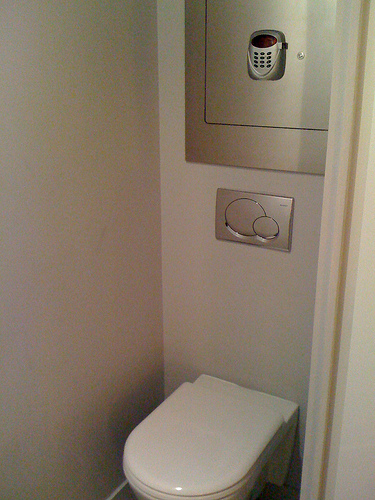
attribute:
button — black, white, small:
[252, 53, 258, 59]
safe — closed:
[203, 0, 337, 130]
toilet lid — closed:
[119, 370, 287, 498]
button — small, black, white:
[265, 50, 271, 55]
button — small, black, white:
[264, 56, 273, 60]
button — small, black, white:
[263, 63, 272, 67]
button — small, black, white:
[251, 63, 257, 68]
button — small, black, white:
[251, 48, 257, 56]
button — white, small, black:
[264, 63, 271, 67]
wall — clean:
[4, 11, 164, 410]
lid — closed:
[106, 368, 309, 498]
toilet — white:
[105, 328, 312, 498]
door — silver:
[198, 1, 335, 136]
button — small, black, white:
[257, 65, 262, 68]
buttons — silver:
[205, 193, 332, 260]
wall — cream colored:
[0, 8, 162, 495]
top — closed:
[91, 354, 318, 496]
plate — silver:
[225, 189, 267, 248]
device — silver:
[247, 29, 287, 79]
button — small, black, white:
[253, 55, 259, 60]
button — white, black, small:
[258, 55, 263, 59]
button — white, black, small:
[253, 60, 258, 64]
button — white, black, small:
[258, 60, 264, 63]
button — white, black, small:
[259, 65, 264, 68]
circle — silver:
[292, 48, 307, 61]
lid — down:
[102, 373, 290, 495]